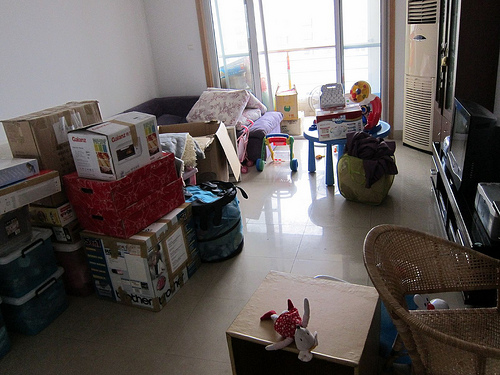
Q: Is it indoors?
A: Yes, it is indoors.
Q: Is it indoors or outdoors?
A: It is indoors.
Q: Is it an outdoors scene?
A: No, it is indoors.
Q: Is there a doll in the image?
A: Yes, there is a doll.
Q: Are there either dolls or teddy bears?
A: Yes, there is a doll.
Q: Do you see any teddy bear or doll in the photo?
A: Yes, there is a doll.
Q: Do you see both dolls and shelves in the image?
A: No, there is a doll but no shelves.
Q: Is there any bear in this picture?
A: No, there are no bears.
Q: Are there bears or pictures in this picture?
A: No, there are no bears or pictures.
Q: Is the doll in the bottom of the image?
A: Yes, the doll is in the bottom of the image.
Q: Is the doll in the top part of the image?
A: No, the doll is in the bottom of the image.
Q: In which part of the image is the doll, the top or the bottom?
A: The doll is in the bottom of the image.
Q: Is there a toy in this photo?
A: Yes, there is a toy.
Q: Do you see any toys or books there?
A: Yes, there is a toy.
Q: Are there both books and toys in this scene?
A: No, there is a toy but no books.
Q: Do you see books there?
A: No, there are no books.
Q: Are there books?
A: No, there are no books.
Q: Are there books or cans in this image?
A: No, there are no books or cans.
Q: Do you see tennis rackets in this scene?
A: No, there are no tennis rackets.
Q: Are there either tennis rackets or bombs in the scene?
A: No, there are no tennis rackets or bombs.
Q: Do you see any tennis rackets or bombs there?
A: No, there are no tennis rackets or bombs.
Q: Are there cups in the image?
A: No, there are no cups.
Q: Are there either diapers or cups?
A: No, there are no cups or diapers.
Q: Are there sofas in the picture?
A: Yes, there is a sofa.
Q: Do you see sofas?
A: Yes, there is a sofa.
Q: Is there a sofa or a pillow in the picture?
A: Yes, there is a sofa.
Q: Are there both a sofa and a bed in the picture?
A: No, there is a sofa but no beds.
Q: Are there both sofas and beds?
A: No, there is a sofa but no beds.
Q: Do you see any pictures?
A: No, there are no pictures.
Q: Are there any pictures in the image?
A: No, there are no pictures.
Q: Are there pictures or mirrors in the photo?
A: No, there are no pictures or mirrors.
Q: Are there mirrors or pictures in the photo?
A: No, there are no pictures or mirrors.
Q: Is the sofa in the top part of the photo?
A: Yes, the sofa is in the top of the image.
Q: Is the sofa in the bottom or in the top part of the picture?
A: The sofa is in the top of the image.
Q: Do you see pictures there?
A: No, there are no pictures.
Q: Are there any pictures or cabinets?
A: No, there are no pictures or cabinets.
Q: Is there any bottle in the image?
A: No, there are no bottles.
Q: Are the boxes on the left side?
A: Yes, the boxes are on the left of the image.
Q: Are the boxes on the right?
A: No, the boxes are on the left of the image.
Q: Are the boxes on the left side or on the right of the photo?
A: The boxes are on the left of the image.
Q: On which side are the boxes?
A: The boxes are on the left of the image.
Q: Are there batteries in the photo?
A: No, there are no batteries.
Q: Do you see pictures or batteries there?
A: No, there are no batteries or pictures.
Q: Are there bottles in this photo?
A: No, there are no bottles.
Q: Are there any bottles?
A: No, there are no bottles.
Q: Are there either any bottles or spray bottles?
A: No, there are no bottles or spray bottles.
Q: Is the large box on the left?
A: Yes, the box is on the left of the image.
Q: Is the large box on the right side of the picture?
A: No, the box is on the left of the image.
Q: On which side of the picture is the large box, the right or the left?
A: The box is on the left of the image.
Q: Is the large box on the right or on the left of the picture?
A: The box is on the left of the image.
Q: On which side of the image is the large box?
A: The box is on the left of the image.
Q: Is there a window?
A: Yes, there is a window.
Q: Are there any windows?
A: Yes, there is a window.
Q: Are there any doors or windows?
A: Yes, there is a window.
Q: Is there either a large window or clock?
A: Yes, there is a large window.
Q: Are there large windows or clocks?
A: Yes, there is a large window.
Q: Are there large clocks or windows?
A: Yes, there is a large window.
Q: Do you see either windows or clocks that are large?
A: Yes, the window is large.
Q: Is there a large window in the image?
A: Yes, there is a large window.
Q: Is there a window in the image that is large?
A: Yes, there is a window that is large.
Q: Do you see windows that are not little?
A: Yes, there is a large window.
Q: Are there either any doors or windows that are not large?
A: No, there is a window but it is large.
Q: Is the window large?
A: Yes, the window is large.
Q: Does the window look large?
A: Yes, the window is large.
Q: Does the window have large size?
A: Yes, the window is large.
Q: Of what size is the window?
A: The window is large.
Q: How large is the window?
A: The window is large.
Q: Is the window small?
A: No, the window is large.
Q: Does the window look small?
A: No, the window is large.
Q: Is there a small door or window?
A: No, there is a window but it is large.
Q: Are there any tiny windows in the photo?
A: No, there is a window but it is large.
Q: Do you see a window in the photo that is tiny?
A: No, there is a window but it is large.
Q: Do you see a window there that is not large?
A: No, there is a window but it is large.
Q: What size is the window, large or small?
A: The window is large.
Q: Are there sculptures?
A: No, there are no sculptures.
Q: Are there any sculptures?
A: No, there are no sculptures.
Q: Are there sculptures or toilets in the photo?
A: No, there are no sculptures or toilets.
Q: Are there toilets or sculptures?
A: No, there are no sculptures or toilets.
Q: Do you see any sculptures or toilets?
A: No, there are no sculptures or toilets.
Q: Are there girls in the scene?
A: No, there are no girls.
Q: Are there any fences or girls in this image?
A: No, there are no girls or fences.